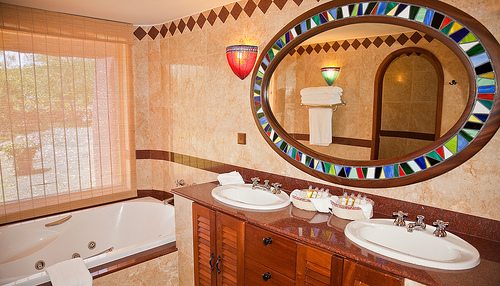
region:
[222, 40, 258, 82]
a red wall light sconce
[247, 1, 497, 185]
a large oval wall mirror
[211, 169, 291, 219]
a white porcelain bathroom sink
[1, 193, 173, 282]
a white whirlpool bathtub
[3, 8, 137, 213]
a screened privacy window looks out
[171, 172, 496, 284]
a rich wooden paneled vanity holds the sinks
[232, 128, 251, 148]
a wall fixture is brown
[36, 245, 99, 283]
a white towel on the tub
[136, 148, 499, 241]
a brown border along the wall at vanity height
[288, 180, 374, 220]
two tubs full of bathroom items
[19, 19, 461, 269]
a picture of a bathroom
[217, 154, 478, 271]
a double sink in the bathroom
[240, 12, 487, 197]
a large colorful mirror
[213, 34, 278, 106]
a light on the wall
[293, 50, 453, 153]
a reflection in the mirror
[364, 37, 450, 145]
a doorway to another room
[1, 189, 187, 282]
a bathtub for the owners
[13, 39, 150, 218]
a window in the bathroom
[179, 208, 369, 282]
drawers on the cabinet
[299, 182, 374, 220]
toothpaste holders for toothbrushes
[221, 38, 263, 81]
a red wall light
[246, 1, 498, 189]
a large wall mirror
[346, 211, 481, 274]
a white sink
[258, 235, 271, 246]
a black cabinet knob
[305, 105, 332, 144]
a white bath towel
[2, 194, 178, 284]
part of a white tub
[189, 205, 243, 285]
a brown cabinet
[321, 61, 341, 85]
a green wall light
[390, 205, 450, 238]
a gray sink faucet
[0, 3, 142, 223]
part of a window shade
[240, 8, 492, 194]
multicolor frame on window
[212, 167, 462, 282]
white sinks on table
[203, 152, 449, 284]
sinks on brown table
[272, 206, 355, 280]
brown table is reflective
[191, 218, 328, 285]
brown cabinets beneath sink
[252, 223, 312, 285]
brown drawers under sink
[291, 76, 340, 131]
white towels in reflection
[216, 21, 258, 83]
red lamp next to sink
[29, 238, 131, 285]
white towel on tub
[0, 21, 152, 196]
tan blind on window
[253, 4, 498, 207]
colorful pattern adorning mirror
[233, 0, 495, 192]
oval bathroom mirror on wall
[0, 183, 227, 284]
white ceramic tub in bathroom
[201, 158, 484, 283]
two white ceramic sinks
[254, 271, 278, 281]
drawer handle on furniture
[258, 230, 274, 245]
drawer handle on furniture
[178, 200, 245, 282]
cupboard space in bathroom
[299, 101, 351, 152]
towel hanging on a rack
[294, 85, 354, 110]
reflection of towels on a shelf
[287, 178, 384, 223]
two small baskets in between sinks